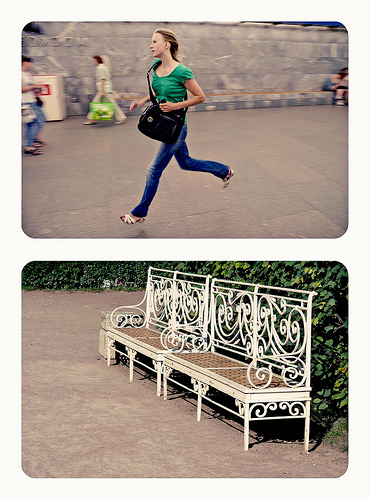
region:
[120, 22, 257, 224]
woman running in the street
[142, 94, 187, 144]
woman holding a black purse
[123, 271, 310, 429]
two white metal benches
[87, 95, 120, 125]
woman carrying a green bag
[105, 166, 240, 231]
woman wearing white sandals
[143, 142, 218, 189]
blue jeans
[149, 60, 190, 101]
woman wearing a green shirt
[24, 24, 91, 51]
a logo on a stone wall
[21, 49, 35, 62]
a person wearing a black cap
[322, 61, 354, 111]
two people sitting on a stone bench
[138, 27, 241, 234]
this is a lady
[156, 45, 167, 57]
the lady has a light skin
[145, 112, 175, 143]
this is a handbag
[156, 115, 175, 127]
the bag is black in color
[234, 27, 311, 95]
this is a wall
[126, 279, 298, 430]
this is a bench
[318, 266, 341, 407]
this is a permanent fence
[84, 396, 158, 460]
this is the ground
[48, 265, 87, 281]
the leaves are green in color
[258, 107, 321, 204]
this is a pavement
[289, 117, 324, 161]
part of a floor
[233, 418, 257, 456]
part of a stand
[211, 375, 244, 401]
edge of a bench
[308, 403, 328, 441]
part of a shade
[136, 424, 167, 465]
part of a floor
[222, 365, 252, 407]
edge of a bench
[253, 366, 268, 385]
part of a metal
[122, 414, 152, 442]
part of a floor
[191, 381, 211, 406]
part of a stand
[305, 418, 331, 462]
edge of a shade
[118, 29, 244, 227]
this is a woman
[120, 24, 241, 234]
the woman is running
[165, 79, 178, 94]
the blouse is green in color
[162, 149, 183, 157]
the trouser is blue in color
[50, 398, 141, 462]
this is the ground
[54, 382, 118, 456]
the ground is sandy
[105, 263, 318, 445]
this is a bench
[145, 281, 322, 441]
the bench is metallic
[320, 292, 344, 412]
these are several leaves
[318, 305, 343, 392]
the leaves are green in color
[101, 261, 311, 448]
white bench with wicker seats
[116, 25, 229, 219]
young girl running down the street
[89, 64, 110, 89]
yellow shirt of woman walking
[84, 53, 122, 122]
woman walking with shopping bag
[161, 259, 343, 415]
bushes in back of bench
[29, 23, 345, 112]
brick wall on side of street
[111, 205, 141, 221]
white sandals of young girl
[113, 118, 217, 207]
blue jeans on young girl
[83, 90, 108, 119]
green shopping bag in lady's hand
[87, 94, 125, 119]
tan pants of woman walking